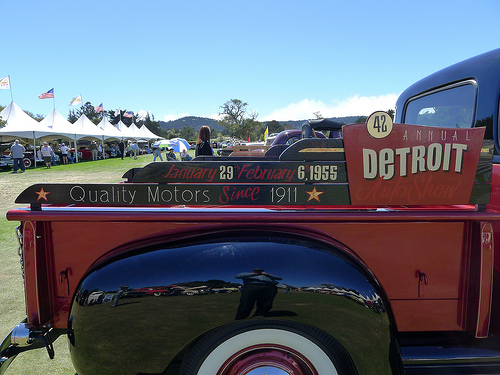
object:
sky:
[0, 0, 499, 121]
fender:
[67, 225, 402, 374]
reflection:
[228, 267, 283, 320]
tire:
[176, 317, 357, 374]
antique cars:
[0, 142, 35, 168]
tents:
[1, 101, 58, 139]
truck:
[0, 48, 499, 375]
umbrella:
[167, 137, 190, 154]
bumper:
[0, 317, 67, 375]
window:
[400, 80, 478, 128]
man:
[40, 140, 55, 169]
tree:
[219, 98, 259, 140]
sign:
[340, 110, 486, 204]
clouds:
[261, 92, 397, 121]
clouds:
[135, 107, 225, 123]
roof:
[0, 102, 54, 133]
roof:
[37, 109, 87, 134]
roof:
[73, 112, 107, 135]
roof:
[95, 115, 125, 136]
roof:
[115, 120, 148, 137]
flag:
[92, 102, 104, 114]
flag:
[123, 110, 135, 118]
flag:
[37, 87, 54, 99]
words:
[68, 161, 338, 204]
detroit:
[361, 142, 467, 180]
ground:
[0, 148, 217, 374]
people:
[10, 138, 27, 174]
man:
[233, 267, 283, 321]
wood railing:
[14, 111, 493, 205]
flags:
[0, 76, 12, 90]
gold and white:
[362, 110, 471, 181]